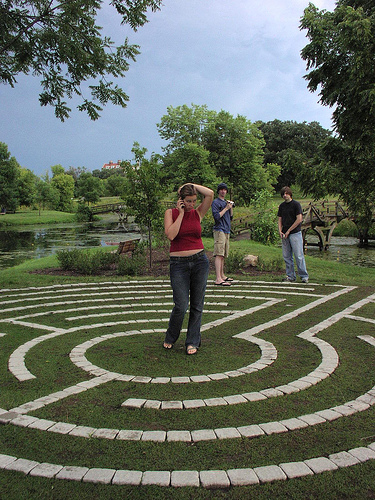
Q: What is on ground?
A: Replica of sundial.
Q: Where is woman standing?
A: Middle of maze.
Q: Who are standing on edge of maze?
A: Two men.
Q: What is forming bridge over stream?
A: The wooden structure.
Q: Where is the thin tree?
A: Growing behind bench.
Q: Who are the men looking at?
A: The woman.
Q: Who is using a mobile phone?
A: The girl.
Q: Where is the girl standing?
A: In the center of a maze.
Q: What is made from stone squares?
A: The maze.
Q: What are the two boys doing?
A: They are looking at the girl.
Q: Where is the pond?
A: Behind the maze.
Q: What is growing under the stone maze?
A: Grass.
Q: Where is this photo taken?
A: At a park.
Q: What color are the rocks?
A: Gray.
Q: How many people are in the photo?
A: Three.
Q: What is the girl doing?
A: Talking on a cell phone.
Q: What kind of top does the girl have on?
A: A tank top.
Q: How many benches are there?
A: One.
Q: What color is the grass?
A: Green.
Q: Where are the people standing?
A: Near a stone maze.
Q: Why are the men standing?
A: They are waiting on the woman to get off of the phone.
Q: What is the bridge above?
A: Water.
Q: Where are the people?
A: A park.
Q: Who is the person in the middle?
A: A woman.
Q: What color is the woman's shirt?
A: Red.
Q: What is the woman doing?
A: Talking on the phone.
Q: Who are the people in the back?
A: Men.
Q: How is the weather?
A: Cloudy.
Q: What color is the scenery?
A: Green.